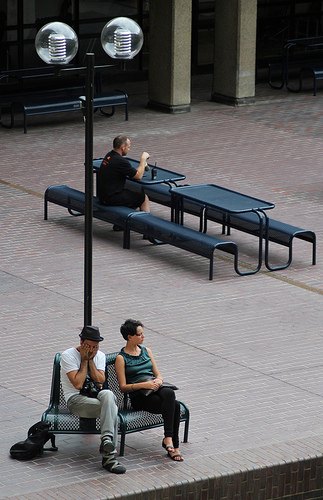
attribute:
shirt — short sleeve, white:
[59, 346, 106, 401]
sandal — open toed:
[161, 442, 175, 454]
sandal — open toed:
[167, 453, 184, 464]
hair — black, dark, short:
[119, 318, 144, 341]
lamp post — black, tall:
[34, 17, 144, 327]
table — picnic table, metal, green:
[169, 183, 275, 273]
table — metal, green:
[85, 156, 188, 225]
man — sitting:
[96, 134, 151, 213]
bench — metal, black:
[42, 352, 190, 452]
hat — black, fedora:
[79, 327, 104, 343]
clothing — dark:
[97, 151, 146, 209]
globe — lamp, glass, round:
[33, 21, 79, 68]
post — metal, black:
[83, 53, 95, 325]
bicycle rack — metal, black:
[265, 40, 321, 95]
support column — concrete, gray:
[209, 2, 257, 104]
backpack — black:
[9, 418, 58, 461]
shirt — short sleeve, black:
[97, 151, 138, 198]